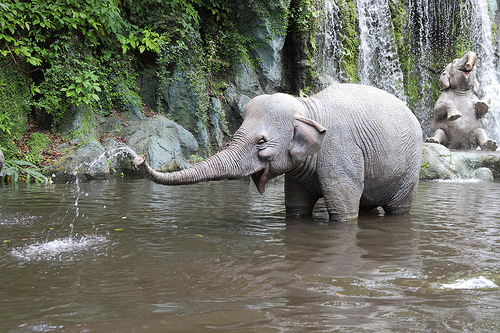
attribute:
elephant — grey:
[180, 48, 447, 226]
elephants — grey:
[119, 43, 496, 228]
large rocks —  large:
[3, 33, 175, 183]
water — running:
[312, 2, 497, 118]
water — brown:
[129, 226, 339, 319]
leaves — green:
[34, 5, 141, 74]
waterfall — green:
[321, 5, 498, 67]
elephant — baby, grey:
[128, 75, 426, 222]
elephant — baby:
[430, 49, 499, 160]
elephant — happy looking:
[114, 63, 456, 227]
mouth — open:
[249, 169, 264, 191]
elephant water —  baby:
[125, 86, 307, 210]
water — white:
[462, 10, 496, 102]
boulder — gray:
[406, 126, 476, 182]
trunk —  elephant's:
[141, 137, 245, 183]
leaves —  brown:
[46, 137, 78, 145]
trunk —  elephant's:
[127, 150, 250, 184]